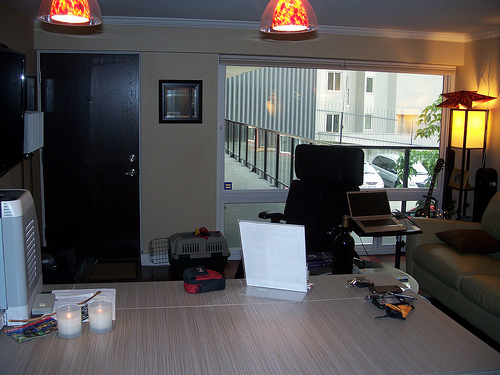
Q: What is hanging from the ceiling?
A: Lights.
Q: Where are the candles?
A: On the table.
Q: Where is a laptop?
A: On a table.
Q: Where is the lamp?
A: In the corner.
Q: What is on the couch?
A: A pillow.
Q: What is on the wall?
A: A picture.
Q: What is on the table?
A: Candles.